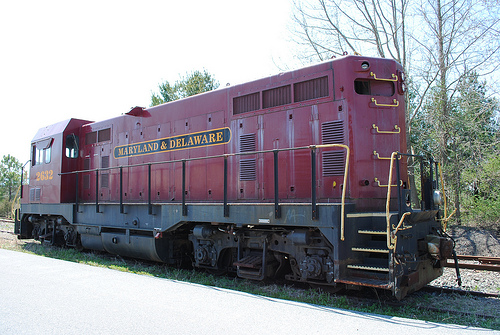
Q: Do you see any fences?
A: No, there are no fences.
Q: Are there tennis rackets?
A: No, there are no tennis rackets.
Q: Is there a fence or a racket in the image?
A: No, there are no rackets or fences.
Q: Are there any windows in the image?
A: Yes, there is a window.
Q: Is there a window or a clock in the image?
A: Yes, there is a window.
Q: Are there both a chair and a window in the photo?
A: No, there is a window but no chairs.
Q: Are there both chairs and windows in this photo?
A: No, there is a window but no chairs.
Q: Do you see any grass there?
A: Yes, there is grass.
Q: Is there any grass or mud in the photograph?
A: Yes, there is grass.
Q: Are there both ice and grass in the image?
A: No, there is grass but no ice.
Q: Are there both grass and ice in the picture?
A: No, there is grass but no ice.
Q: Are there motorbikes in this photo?
A: No, there are no motorbikes.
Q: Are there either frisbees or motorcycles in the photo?
A: No, there are no motorcycles or frisbees.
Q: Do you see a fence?
A: No, there are no fences.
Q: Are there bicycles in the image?
A: No, there are no bicycles.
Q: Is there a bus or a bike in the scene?
A: No, there are no bikes or buses.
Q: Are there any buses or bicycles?
A: No, there are no bicycles or buses.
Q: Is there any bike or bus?
A: No, there are no bikes or buses.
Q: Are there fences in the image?
A: No, there are no fences.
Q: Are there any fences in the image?
A: No, there are no fences.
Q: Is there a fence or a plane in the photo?
A: No, there are no fences or airplanes.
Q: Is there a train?
A: Yes, there is a train.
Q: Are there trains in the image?
A: Yes, there is a train.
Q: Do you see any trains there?
A: Yes, there is a train.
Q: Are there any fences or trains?
A: Yes, there is a train.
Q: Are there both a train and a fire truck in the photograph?
A: No, there is a train but no fire trucks.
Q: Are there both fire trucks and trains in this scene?
A: No, there is a train but no fire trucks.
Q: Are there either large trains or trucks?
A: Yes, there is a large train.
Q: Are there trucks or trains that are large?
A: Yes, the train is large.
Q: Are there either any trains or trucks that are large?
A: Yes, the train is large.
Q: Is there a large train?
A: Yes, there is a large train.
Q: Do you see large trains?
A: Yes, there is a large train.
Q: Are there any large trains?
A: Yes, there is a large train.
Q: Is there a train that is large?
A: Yes, there is a train that is large.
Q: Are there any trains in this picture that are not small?
A: Yes, there is a large train.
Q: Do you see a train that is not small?
A: Yes, there is a large train.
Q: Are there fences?
A: No, there are no fences.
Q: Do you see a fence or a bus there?
A: No, there are no fences or buses.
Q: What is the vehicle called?
A: The vehicle is a train.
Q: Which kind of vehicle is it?
A: The vehicle is a train.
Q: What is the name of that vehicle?
A: This is a train.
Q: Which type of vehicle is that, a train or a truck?
A: This is a train.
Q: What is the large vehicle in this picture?
A: The vehicle is a train.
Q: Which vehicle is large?
A: The vehicle is a train.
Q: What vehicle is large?
A: The vehicle is a train.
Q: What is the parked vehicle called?
A: The vehicle is a train.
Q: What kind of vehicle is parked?
A: The vehicle is a train.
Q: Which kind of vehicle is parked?
A: The vehicle is a train.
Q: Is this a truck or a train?
A: This is a train.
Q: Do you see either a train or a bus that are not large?
A: No, there is a train but it is large.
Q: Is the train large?
A: Yes, the train is large.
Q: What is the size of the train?
A: The train is large.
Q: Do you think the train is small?
A: No, the train is large.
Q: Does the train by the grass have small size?
A: No, the train is large.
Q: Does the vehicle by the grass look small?
A: No, the train is large.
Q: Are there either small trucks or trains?
A: No, there is a train but it is large.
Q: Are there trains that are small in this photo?
A: No, there is a train but it is large.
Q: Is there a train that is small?
A: No, there is a train but it is large.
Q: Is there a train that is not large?
A: No, there is a train but it is large.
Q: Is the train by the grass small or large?
A: The train is large.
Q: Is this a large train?
A: Yes, this is a large train.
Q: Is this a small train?
A: No, this is a large train.